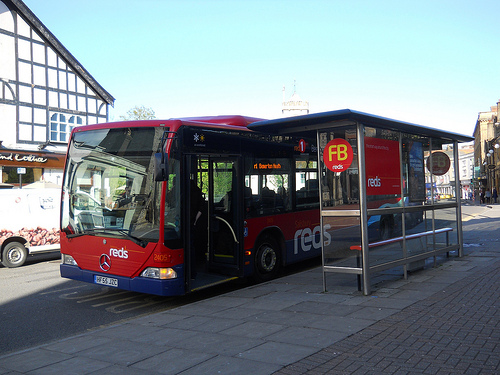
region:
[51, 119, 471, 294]
bus is red and blue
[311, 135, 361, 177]
Red circled sign with FB in yellow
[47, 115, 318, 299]
Red and blue city bus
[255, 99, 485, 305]
Seating for bus stop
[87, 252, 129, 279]
Volkswagen symbol on a bus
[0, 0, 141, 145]
Top half of a building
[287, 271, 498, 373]
Brick paved sidewalk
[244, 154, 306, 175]
Bus sign showing bus information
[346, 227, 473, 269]
Red and black metal bench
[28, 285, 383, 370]
Cement sidewalk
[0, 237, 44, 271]
Tire on a white and brown vehicle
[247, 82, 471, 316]
bus stop is clear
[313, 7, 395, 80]
part of the sky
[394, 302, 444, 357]
part of the floor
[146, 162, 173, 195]
part of a side mirror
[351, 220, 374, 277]
edge of a metal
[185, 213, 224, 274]
part of a door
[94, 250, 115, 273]
part of a logo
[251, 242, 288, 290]
part of a rim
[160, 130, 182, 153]
part of a handle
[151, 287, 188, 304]
edge of a bus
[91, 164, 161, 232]
part of a window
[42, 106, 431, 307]
bus on a street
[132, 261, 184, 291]
front headlight on a vehicle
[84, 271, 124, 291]
licence plate on a vehicle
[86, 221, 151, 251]
front windshield wiper on a vehicle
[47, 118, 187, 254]
front windshield on a vehicle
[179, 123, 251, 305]
side door on a bus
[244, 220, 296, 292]
front wheel on a vehicle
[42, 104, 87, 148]
windows on a building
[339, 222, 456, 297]
bench in a shelter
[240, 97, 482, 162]
roof on a shelter